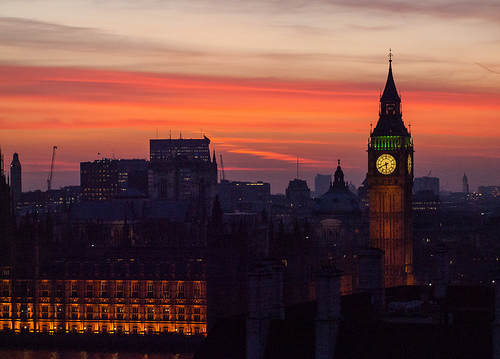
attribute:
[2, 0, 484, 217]
sky — clear, orange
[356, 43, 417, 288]
building — tall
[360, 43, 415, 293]
building — tall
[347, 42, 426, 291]
tower — brick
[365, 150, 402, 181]
clock — small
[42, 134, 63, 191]
crane — tall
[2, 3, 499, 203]
sky — white, orange, cloudy, hazy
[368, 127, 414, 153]
lights — green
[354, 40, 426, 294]
tower — large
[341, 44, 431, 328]
clock tower — illuminated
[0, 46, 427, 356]
building — illuminated at night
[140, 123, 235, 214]
building — distant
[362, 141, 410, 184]
clock face — illuminated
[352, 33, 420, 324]
clock tower — tall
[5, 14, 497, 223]
sky — red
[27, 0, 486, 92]
clouds — hazy, grey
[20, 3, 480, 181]
sky — pink-orange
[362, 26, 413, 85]
tower top — pointed, metal, decorative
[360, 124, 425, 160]
barricade — eerie, green, lit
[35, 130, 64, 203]
crane head — erect, vertical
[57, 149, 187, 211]
building — squat, square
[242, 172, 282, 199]
lights — row, yellow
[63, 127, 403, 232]
city skyline — at dusk, dark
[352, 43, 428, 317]
clock tower — illuminated, tall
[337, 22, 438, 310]
clock tower — big ben